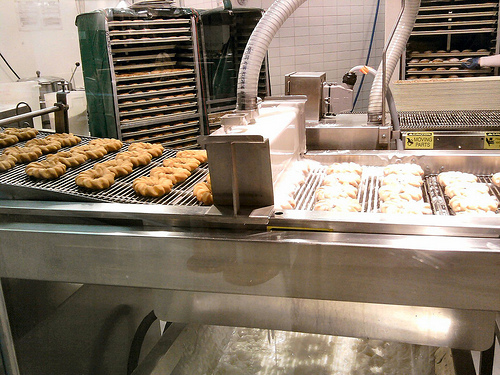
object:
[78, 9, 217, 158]
donut cart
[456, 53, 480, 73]
hand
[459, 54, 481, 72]
glove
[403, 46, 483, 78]
racks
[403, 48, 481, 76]
donuts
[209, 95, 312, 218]
section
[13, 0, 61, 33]
signs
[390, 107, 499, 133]
conveyor belt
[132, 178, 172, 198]
donut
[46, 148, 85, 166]
donut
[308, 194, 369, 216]
donut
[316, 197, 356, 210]
powder sugar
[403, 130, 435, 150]
sticker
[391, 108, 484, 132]
conveyor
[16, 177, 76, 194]
conveyor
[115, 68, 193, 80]
trays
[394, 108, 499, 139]
machines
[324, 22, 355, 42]
tiles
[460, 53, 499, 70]
arm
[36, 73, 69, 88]
container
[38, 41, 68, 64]
wall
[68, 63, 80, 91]
handle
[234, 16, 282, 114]
hoses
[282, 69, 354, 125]
machine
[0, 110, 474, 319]
machine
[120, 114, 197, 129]
pans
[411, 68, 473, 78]
pans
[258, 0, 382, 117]
wall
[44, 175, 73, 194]
rollers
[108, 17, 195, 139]
rack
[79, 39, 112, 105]
cover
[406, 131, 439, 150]
sticker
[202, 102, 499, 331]
equipment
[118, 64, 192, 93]
doughnuts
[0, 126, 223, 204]
six lines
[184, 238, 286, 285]
reflection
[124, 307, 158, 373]
black hose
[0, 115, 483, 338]
silver conveyor